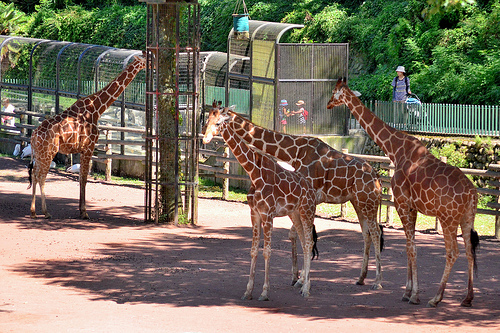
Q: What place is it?
A: It is a zoo.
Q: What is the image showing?
A: It is showing a zoo.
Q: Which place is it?
A: It is a zoo.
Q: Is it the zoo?
A: Yes, it is the zoo.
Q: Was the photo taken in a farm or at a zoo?
A: It was taken at a zoo.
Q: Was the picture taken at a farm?
A: No, the picture was taken in a zoo.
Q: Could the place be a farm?
A: No, it is a zoo.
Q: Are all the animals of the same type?
A: Yes, all the animals are giraffes.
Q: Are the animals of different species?
A: No, all the animals are giraffes.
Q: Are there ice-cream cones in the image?
A: No, there are no ice-cream cones.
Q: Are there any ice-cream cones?
A: No, there are no ice-cream cones.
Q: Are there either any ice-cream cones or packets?
A: No, there are no ice-cream cones or packets.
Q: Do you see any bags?
A: No, there are no bags.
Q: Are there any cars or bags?
A: No, there are no bags or cars.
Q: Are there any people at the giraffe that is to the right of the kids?
A: Yes, there are people at the giraffe.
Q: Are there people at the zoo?
A: Yes, there are people at the zoo.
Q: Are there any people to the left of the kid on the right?
A: Yes, there are people to the left of the kid.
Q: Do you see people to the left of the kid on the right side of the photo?
A: Yes, there are people to the left of the kid.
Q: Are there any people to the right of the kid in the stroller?
A: No, the people are to the left of the kid.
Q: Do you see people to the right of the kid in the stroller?
A: No, the people are to the left of the kid.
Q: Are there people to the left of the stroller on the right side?
A: Yes, there are people to the left of the stroller.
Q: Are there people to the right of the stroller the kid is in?
A: No, the people are to the left of the stroller.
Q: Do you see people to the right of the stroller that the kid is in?
A: No, the people are to the left of the stroller.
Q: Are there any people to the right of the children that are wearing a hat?
A: Yes, there are people to the right of the children.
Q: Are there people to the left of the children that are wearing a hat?
A: No, the people are to the right of the children.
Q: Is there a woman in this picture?
A: Yes, there is a woman.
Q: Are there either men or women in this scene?
A: Yes, there is a woman.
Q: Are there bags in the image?
A: No, there are no bags.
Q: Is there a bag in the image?
A: No, there are no bags.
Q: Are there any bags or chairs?
A: No, there are no bags or chairs.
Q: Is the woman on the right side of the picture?
A: Yes, the woman is on the right of the image.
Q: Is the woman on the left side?
A: No, the woman is on the right of the image.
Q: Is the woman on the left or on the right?
A: The woman is on the right of the image.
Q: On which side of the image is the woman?
A: The woman is on the right of the image.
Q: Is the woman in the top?
A: Yes, the woman is in the top of the image.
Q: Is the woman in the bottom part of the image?
A: No, the woman is in the top of the image.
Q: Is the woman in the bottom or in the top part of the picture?
A: The woman is in the top of the image.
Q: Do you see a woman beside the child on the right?
A: Yes, there is a woman beside the child.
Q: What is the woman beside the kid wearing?
A: The woman is wearing a hat.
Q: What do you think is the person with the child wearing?
A: The woman is wearing a hat.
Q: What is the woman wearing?
A: The woman is wearing a hat.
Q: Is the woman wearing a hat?
A: Yes, the woman is wearing a hat.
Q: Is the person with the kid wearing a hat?
A: Yes, the woman is wearing a hat.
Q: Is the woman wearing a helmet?
A: No, the woman is wearing a hat.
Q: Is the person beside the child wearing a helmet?
A: No, the woman is wearing a hat.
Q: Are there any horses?
A: No, there are no horses.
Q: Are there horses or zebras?
A: No, there are no horses or zebras.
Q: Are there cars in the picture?
A: No, there are no cars.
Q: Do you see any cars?
A: No, there are no cars.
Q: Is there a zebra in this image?
A: No, there are no zebras.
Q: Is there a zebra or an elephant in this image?
A: No, there are no zebras or elephants.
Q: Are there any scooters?
A: No, there are no scooters.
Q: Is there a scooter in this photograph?
A: No, there are no scooters.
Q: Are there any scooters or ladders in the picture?
A: No, there are no scooters or ladders.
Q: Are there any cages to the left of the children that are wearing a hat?
A: Yes, there is a cage to the left of the kids.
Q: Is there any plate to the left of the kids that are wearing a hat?
A: No, there is a cage to the left of the children.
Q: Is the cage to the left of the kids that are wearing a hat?
A: Yes, the cage is to the left of the children.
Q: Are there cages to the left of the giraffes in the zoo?
A: Yes, there is a cage to the left of the giraffes.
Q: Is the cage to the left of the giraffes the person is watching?
A: Yes, the cage is to the left of the giraffes.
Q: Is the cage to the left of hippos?
A: No, the cage is to the left of the giraffes.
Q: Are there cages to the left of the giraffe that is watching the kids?
A: Yes, there is a cage to the left of the giraffe.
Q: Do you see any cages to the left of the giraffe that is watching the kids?
A: Yes, there is a cage to the left of the giraffe.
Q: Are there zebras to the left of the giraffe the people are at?
A: No, there is a cage to the left of the giraffe.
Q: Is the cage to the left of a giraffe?
A: Yes, the cage is to the left of a giraffe.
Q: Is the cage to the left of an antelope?
A: No, the cage is to the left of a giraffe.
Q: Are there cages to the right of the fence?
A: Yes, there is a cage to the right of the fence.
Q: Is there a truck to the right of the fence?
A: No, there is a cage to the right of the fence.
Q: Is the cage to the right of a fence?
A: Yes, the cage is to the right of a fence.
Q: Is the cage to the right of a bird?
A: No, the cage is to the right of a fence.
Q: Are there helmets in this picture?
A: No, there are no helmets.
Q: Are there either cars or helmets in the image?
A: No, there are no helmets or cars.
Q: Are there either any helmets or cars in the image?
A: No, there are no helmets or cars.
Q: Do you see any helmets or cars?
A: No, there are no helmets or cars.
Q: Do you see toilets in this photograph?
A: No, there are no toilets.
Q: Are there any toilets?
A: No, there are no toilets.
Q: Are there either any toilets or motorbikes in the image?
A: No, there are no toilets or motorbikes.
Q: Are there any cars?
A: No, there are no cars.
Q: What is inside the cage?
A: The tree is inside the cage.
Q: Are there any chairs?
A: No, there are no chairs.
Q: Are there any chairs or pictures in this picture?
A: No, there are no chairs or pictures.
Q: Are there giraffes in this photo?
A: Yes, there are giraffes.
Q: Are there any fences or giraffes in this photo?
A: Yes, there are giraffes.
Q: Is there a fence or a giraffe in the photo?
A: Yes, there are giraffes.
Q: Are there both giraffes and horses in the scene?
A: No, there are giraffes but no horses.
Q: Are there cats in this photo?
A: No, there are no cats.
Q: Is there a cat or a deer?
A: No, there are no cats or deer.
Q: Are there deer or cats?
A: No, there are no cats or deer.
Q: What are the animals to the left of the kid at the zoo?
A: The animals are giraffes.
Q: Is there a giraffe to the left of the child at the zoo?
A: Yes, there are giraffes to the left of the kid.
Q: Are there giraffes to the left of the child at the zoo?
A: Yes, there are giraffes to the left of the kid.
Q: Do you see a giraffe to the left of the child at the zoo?
A: Yes, there are giraffes to the left of the kid.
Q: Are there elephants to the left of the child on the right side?
A: No, there are giraffes to the left of the kid.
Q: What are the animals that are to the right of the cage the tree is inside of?
A: The animals are giraffes.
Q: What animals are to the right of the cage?
A: The animals are giraffes.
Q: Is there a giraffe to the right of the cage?
A: Yes, there are giraffes to the right of the cage.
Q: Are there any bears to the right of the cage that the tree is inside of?
A: No, there are giraffes to the right of the cage.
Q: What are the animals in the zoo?
A: The animals are giraffes.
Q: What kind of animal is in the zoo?
A: The animals are giraffes.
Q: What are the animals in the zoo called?
A: The animals are giraffes.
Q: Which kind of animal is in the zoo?
A: The animals are giraffes.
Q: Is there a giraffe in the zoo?
A: Yes, there are giraffes in the zoo.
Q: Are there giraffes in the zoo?
A: Yes, there are giraffes in the zoo.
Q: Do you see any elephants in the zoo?
A: No, there are giraffes in the zoo.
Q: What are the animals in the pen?
A: The animals are giraffes.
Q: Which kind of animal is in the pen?
A: The animals are giraffes.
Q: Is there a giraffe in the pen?
A: Yes, there are giraffes in the pen.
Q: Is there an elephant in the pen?
A: No, there are giraffes in the pen.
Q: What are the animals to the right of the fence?
A: The animals are giraffes.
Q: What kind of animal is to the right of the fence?
A: The animals are giraffes.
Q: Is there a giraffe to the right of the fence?
A: Yes, there are giraffes to the right of the fence.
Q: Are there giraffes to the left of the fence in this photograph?
A: No, the giraffes are to the right of the fence.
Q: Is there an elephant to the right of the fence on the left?
A: No, there are giraffes to the right of the fence.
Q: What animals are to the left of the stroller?
A: The animals are giraffes.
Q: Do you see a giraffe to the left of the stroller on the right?
A: Yes, there are giraffes to the left of the stroller.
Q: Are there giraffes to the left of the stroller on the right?
A: Yes, there are giraffes to the left of the stroller.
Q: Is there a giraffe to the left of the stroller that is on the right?
A: Yes, there are giraffes to the left of the stroller.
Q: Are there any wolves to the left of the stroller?
A: No, there are giraffes to the left of the stroller.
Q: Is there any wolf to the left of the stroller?
A: No, there are giraffes to the left of the stroller.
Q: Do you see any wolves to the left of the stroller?
A: No, there are giraffes to the left of the stroller.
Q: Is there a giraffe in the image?
A: Yes, there is a giraffe.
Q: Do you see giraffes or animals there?
A: Yes, there is a giraffe.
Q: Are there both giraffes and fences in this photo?
A: Yes, there are both a giraffe and a fence.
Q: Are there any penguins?
A: No, there are no penguins.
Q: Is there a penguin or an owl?
A: No, there are no penguins or owls.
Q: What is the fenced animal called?
A: The animal is a giraffe.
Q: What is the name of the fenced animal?
A: The animal is a giraffe.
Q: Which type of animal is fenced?
A: The animal is a giraffe.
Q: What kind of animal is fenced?
A: The animal is a giraffe.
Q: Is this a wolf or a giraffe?
A: This is a giraffe.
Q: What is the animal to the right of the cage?
A: The animal is a giraffe.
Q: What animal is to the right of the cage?
A: The animal is a giraffe.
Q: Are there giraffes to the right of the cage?
A: Yes, there is a giraffe to the right of the cage.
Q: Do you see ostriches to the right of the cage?
A: No, there is a giraffe to the right of the cage.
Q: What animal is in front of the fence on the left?
A: The giraffe is in front of the fence.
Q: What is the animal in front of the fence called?
A: The animal is a giraffe.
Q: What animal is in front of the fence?
A: The animal is a giraffe.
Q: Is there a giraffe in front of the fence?
A: Yes, there is a giraffe in front of the fence.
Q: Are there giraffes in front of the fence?
A: Yes, there is a giraffe in front of the fence.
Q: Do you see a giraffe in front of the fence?
A: Yes, there is a giraffe in front of the fence.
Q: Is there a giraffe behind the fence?
A: No, the giraffe is in front of the fence.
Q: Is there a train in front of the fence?
A: No, there is a giraffe in front of the fence.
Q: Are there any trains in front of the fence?
A: No, there is a giraffe in front of the fence.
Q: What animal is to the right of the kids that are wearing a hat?
A: The animal is a giraffe.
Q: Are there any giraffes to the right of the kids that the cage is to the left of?
A: Yes, there is a giraffe to the right of the children.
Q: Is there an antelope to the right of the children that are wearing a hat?
A: No, there is a giraffe to the right of the children.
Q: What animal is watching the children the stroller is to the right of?
A: The giraffe is watching the children.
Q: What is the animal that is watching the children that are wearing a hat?
A: The animal is a giraffe.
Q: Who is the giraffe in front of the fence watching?
A: The giraffe is watching the kids.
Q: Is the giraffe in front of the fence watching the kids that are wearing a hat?
A: Yes, the giraffe is watching the children.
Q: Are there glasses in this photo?
A: No, there are no glasses.